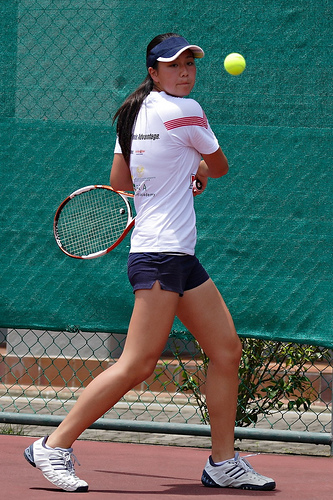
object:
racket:
[52, 178, 202, 260]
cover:
[0, 1, 332, 348]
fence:
[0, 0, 332, 442]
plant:
[156, 326, 330, 449]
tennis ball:
[223, 52, 246, 77]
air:
[0, 2, 106, 162]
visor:
[154, 37, 204, 63]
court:
[0, 434, 332, 499]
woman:
[23, 33, 276, 493]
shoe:
[23, 435, 89, 493]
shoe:
[199, 454, 276, 492]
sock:
[43, 443, 53, 451]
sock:
[216, 458, 234, 467]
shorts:
[126, 252, 211, 297]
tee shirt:
[113, 91, 221, 255]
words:
[131, 132, 160, 143]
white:
[156, 97, 177, 114]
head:
[145, 33, 197, 99]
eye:
[168, 62, 179, 69]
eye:
[186, 61, 195, 67]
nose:
[178, 62, 190, 78]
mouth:
[177, 81, 191, 87]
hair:
[110, 32, 185, 180]